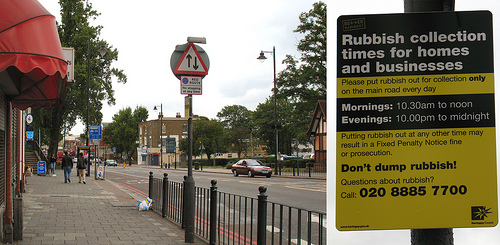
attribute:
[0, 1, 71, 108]
awning — red 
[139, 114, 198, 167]
building — Brown 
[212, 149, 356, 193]
car — red 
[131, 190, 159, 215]
bag — small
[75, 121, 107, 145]
sign — blue 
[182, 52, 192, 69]
arrow — Black 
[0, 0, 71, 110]
awing — Red 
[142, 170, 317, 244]
fence — Black 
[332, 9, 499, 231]
sign —  yellow, yellow 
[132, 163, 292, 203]
rail — black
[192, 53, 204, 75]
arrow — black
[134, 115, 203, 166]
building — brown